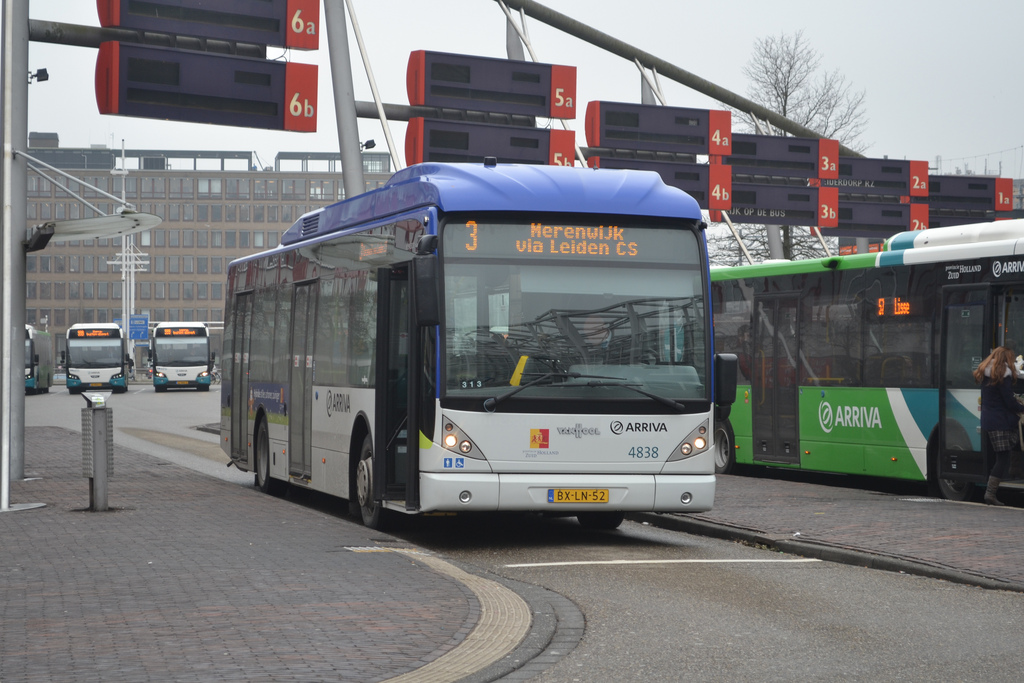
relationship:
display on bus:
[445, 210, 706, 265] [217, 159, 718, 532]